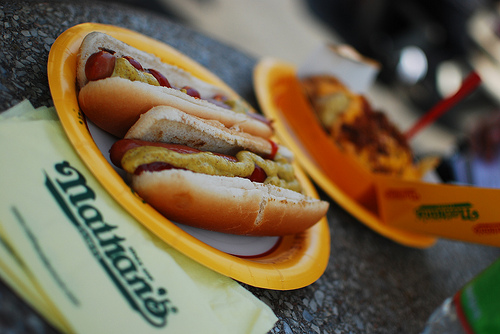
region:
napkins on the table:
[6, 112, 214, 332]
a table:
[15, 0, 445, 325]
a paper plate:
[46, 25, 311, 285]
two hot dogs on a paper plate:
[60, 20, 340, 265]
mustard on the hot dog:
[130, 142, 280, 167]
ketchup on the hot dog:
[255, 140, 287, 145]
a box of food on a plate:
[275, 65, 465, 210]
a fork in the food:
[415, 66, 476, 136]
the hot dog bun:
[148, 165, 323, 241]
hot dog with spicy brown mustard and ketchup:
[76, 25, 278, 142]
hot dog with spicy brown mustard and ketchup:
[108, 99, 330, 244]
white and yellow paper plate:
[45, 14, 342, 299]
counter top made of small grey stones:
[3, 4, 498, 330]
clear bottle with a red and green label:
[391, 250, 498, 330]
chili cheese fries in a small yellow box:
[249, 48, 499, 250]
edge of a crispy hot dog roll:
[136, 167, 329, 249]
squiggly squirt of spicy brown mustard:
[111, 142, 296, 183]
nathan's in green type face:
[37, 152, 181, 332]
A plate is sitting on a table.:
[43, 18, 333, 293]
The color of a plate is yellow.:
[43, 20, 332, 295]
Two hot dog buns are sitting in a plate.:
[70, 27, 332, 241]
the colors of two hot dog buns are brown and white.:
[75, 20, 332, 240]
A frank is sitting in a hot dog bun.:
[105, 128, 307, 190]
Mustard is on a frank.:
[120, 132, 307, 197]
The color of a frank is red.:
[107, 129, 276, 180]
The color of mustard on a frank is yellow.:
[117, 139, 302, 193]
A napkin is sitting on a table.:
[0, 95, 285, 332]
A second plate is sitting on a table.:
[246, 44, 498, 249]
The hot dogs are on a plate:
[55, 30, 335, 277]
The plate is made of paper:
[50, 22, 320, 304]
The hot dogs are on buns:
[62, 26, 338, 276]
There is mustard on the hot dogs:
[50, 24, 349, 294]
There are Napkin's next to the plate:
[3, 109, 266, 332]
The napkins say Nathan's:
[6, 107, 246, 332]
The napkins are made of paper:
[5, 117, 250, 332]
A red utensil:
[395, 59, 484, 160]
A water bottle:
[425, 250, 498, 326]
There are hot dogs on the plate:
[56, 25, 348, 269]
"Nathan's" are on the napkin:
[39, 153, 209, 327]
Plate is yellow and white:
[33, 18, 387, 303]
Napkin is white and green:
[11, 109, 281, 329]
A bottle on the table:
[407, 230, 498, 318]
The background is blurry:
[236, 3, 498, 156]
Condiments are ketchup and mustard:
[78, 34, 338, 239]